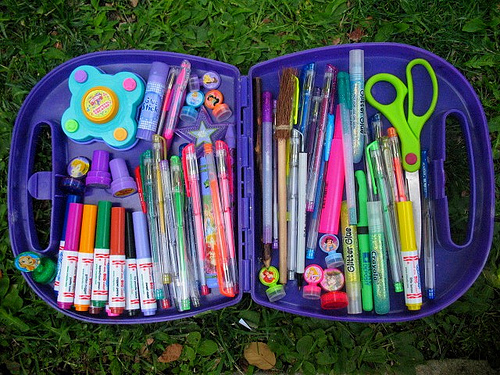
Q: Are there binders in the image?
A: No, there are no binders.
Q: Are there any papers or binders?
A: No, there are no binders or papers.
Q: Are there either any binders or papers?
A: No, there are no binders or papers.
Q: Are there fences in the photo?
A: No, there are no fences.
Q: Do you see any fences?
A: No, there are no fences.